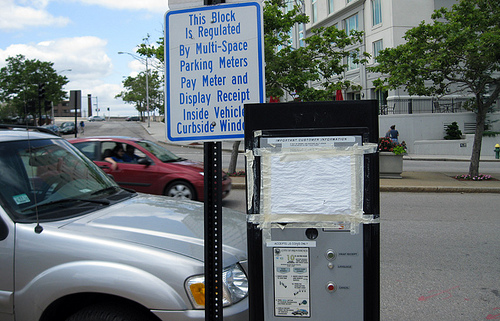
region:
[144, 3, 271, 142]
Instructional white sign with blue writing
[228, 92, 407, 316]
Parking meter with paper taped on the face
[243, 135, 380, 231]
White paper with tape on all sides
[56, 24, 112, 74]
White clouds in a blue sky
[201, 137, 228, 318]
Metal pole for a sign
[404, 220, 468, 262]
Grey pavement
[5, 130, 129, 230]
Front windshield on a vehicle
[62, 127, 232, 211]
Red car with window down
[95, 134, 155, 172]
Persons arm hanging out of a car window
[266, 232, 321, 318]
Instructions on the front of a parking meter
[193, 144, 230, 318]
black metal street sign pole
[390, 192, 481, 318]
grey asphalt on road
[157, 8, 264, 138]
blue and white street sign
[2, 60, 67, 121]
tree with green leaves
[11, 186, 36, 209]
sticker on wind shield of car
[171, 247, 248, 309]
headlight on front of grey car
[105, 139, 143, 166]
people in red car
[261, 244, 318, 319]
sticker on front of parking meter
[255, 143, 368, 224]
paper taped over display of parking meter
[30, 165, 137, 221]
black wind shield wipers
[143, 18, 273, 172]
sign is blue and white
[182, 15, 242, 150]
blue letters on sign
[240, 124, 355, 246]
white taped-on sign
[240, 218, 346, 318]
grey parking meter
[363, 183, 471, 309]
light grey road behind meter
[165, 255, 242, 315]
orange headlight on van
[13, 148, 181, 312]
silver van is parked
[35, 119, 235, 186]
red car behind silver van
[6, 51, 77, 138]
tall tree behind silver van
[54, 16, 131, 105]
sky is blue with few clouds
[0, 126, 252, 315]
silver car parked on street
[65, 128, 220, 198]
red car driving down road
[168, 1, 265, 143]
blue and white sign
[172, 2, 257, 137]
sign with rules about parking on them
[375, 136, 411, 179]
large potted plant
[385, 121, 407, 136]
person walking behind potted plant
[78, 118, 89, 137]
person walking in the background of red car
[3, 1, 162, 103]
white clouds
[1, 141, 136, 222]
front window of silver car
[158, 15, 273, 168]
White rectangle sign on pole.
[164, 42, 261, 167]
Blue writing on white sign.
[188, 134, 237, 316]
Sign attached to black pole.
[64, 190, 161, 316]
Silver car parked near pole.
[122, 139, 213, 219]
Red car driving on road.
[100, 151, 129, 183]
Person's arm sticking out of car.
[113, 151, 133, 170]
Person wearing blue shirt.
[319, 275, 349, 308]
Red button on sign.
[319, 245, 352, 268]
Green button on sign.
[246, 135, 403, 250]
White paper taped to sign.